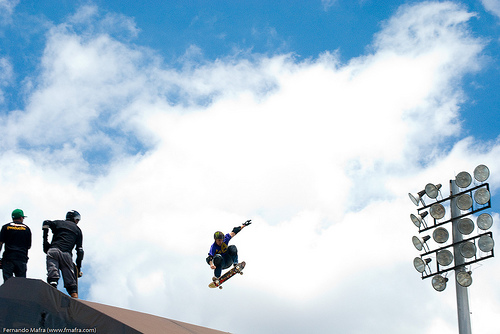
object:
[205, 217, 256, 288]
skateboarding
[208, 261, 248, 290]
skateboard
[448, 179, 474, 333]
light stand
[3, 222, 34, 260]
shirt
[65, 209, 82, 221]
helmet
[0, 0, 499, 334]
clouds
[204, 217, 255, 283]
man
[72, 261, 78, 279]
skateboard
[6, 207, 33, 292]
person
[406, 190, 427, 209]
light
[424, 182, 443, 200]
light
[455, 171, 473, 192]
light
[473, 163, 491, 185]
light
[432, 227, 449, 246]
light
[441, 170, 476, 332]
pole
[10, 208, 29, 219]
cap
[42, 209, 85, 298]
man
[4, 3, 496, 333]
sky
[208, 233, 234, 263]
t-shirt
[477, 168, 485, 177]
bulb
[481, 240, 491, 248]
bulb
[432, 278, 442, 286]
bulb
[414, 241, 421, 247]
bulb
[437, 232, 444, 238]
bulb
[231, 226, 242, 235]
elbow pad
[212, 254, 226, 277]
leg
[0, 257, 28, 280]
pants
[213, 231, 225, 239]
helmet